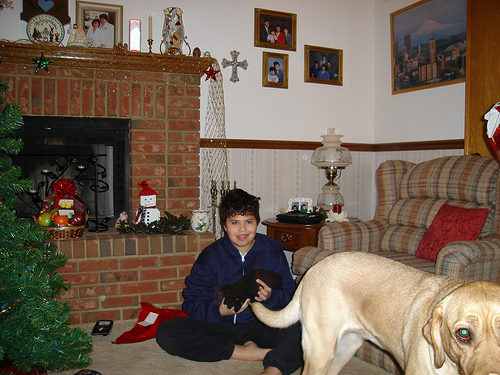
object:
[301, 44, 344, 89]
photos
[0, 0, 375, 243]
wall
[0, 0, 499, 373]
room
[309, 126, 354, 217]
lamp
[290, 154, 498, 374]
chair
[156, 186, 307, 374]
boy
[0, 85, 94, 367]
tree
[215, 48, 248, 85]
cross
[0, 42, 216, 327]
fireplace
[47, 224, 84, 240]
basket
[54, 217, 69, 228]
fruit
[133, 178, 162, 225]
decoration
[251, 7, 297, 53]
pictures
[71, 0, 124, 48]
picture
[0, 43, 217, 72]
mantel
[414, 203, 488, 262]
cushion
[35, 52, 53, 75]
star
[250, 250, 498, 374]
dog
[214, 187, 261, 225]
hair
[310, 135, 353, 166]
shade